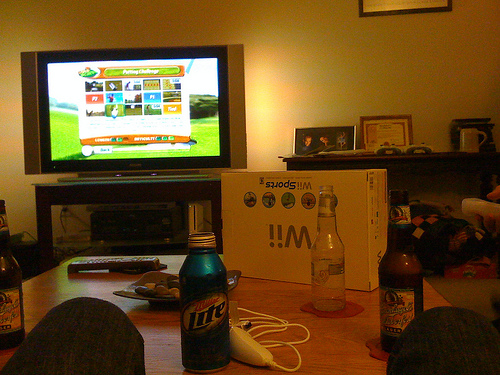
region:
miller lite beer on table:
[176, 210, 236, 372]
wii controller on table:
[203, 278, 311, 373]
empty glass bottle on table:
[303, 183, 353, 315]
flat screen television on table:
[14, 23, 281, 179]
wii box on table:
[214, 150, 399, 300]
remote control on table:
[56, 248, 161, 280]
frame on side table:
[359, 98, 424, 159]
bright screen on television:
[49, 56, 219, 161]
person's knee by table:
[382, 291, 489, 372]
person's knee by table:
[7, 273, 162, 374]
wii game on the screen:
[45, 62, 222, 159]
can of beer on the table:
[177, 228, 228, 370]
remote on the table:
[67, 252, 159, 271]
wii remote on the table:
[230, 301, 312, 371]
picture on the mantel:
[290, 121, 360, 157]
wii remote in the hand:
[447, 180, 498, 230]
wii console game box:
[222, 173, 309, 279]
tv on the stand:
[14, 35, 248, 174]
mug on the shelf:
[452, 123, 487, 155]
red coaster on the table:
[319, 308, 361, 324]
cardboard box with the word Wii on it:
[218, 166, 390, 293]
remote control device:
[64, 253, 172, 279]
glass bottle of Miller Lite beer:
[177, 229, 234, 373]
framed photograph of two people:
[291, 123, 358, 159]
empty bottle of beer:
[307, 182, 349, 314]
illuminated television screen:
[16, 41, 236, 186]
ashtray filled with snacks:
[111, 266, 245, 308]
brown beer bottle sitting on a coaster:
[363, 185, 428, 362]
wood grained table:
[0, 251, 456, 373]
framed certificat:
[358, 111, 414, 153]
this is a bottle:
[166, 214, 236, 372]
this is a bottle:
[282, 184, 351, 318]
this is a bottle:
[383, 180, 430, 344]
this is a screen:
[24, 34, 248, 180]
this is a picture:
[279, 101, 356, 176]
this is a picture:
[357, 95, 413, 167]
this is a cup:
[454, 107, 488, 161]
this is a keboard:
[63, 246, 165, 295]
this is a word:
[256, 208, 312, 268]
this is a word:
[172, 291, 229, 335]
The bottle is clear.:
[304, 165, 354, 318]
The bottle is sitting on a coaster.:
[292, 178, 369, 327]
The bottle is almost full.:
[361, 175, 438, 367]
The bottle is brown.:
[359, 171, 434, 368]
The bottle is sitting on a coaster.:
[361, 185, 439, 364]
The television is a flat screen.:
[23, 42, 243, 177]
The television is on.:
[18, 34, 255, 189]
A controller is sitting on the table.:
[32, 231, 187, 306]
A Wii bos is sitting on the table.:
[193, 152, 445, 357]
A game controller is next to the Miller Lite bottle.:
[176, 223, 311, 373]